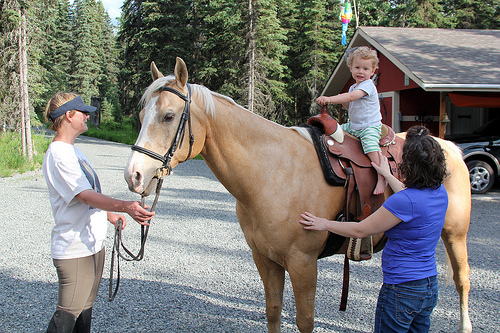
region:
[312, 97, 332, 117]
Horn on saddle of horse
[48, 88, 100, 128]
Visor worn by woman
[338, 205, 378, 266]
Stirrups connected to the saddle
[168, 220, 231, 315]
Gravel parking lot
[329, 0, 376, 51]
Colorful windsock hung on building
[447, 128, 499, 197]
Car parked in a gravel parking lot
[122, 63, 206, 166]
Bridle placed on a horse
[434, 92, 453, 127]
Old-fashioned dinner bell on country home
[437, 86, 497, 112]
Scarlet awning for front porch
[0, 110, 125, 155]
Gravel driveway heading off into the distance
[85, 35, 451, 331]
Little girl is riding a horse.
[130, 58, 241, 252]
The horse has a white design on its face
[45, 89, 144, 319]
The woman is leading the horse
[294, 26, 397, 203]
The little girl is sitting on the saddle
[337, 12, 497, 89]
A red barn in the background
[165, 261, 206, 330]
Gravel stones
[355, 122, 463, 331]
Mom is holding her daughters leg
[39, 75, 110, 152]
Woman is wearing visor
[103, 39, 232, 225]
The horse looks sleepy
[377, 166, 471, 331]
Woman is wearing blue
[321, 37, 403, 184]
blonde kid with no shoes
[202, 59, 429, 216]
kid sitting on horse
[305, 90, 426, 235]
horse wearing a saddle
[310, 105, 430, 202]
saddle is brown and black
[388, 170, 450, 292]
woman wearing blue shirt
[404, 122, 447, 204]
woman looking at kid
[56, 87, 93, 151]
lady wearing black cap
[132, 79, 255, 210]
horse has on dark bridle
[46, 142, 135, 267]
white shirt with picture on front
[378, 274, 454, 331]
woman wearing blue jeans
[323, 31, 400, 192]
A scared looking boy.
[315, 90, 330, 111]
A hand on the saddle.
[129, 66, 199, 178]
the reign harness on head.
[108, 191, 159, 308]
The reigns in hand.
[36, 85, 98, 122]
A womens blue visor.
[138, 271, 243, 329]
Gravel and pebbles on road.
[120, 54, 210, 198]
The head of the horse.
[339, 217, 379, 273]
The stir up ofr the saddle.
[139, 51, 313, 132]
The horses white mane.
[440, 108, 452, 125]
A light on the wooden column.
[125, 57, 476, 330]
tan horse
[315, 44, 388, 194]
child riding horse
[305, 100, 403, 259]
leather saddle on horse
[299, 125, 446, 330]
woman holding onto the child riding the horse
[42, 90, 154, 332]
woman holding the horse's bridle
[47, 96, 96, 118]
blue visor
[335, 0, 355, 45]
colorful windsock in background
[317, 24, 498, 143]
red building in background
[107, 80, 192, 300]
horse's bridle and reins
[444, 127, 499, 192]
car in the background